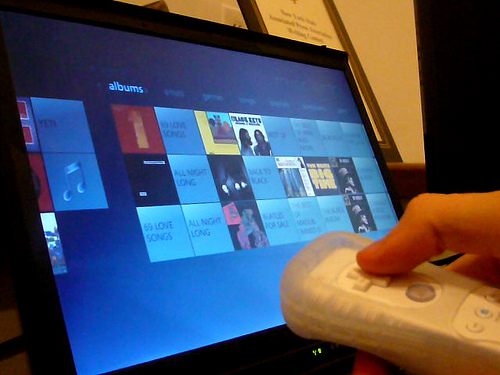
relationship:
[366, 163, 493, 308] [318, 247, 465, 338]
thumb on button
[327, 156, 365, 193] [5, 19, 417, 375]
square on screen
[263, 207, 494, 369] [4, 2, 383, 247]
remote used on computer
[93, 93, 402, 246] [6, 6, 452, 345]
albums on computer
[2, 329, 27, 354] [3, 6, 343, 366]
cord behind computer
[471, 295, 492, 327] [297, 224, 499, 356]
button on remote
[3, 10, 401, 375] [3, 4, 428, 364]
screen on television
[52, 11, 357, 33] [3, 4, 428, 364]
rim on television